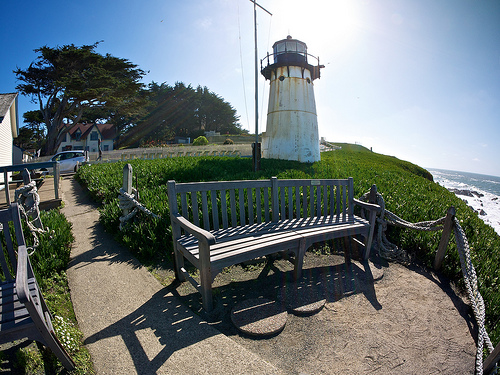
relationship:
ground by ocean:
[74, 141, 499, 310] [421, 167, 499, 238]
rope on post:
[376, 192, 496, 374] [433, 204, 460, 273]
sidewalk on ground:
[59, 173, 284, 375] [74, 141, 499, 310]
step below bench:
[230, 295, 288, 338] [165, 176, 381, 311]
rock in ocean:
[453, 186, 475, 197] [421, 167, 499, 238]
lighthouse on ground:
[260, 32, 325, 167] [74, 141, 499, 310]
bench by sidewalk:
[165, 176, 381, 311] [59, 173, 284, 375]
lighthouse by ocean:
[260, 32, 325, 167] [421, 167, 499, 238]